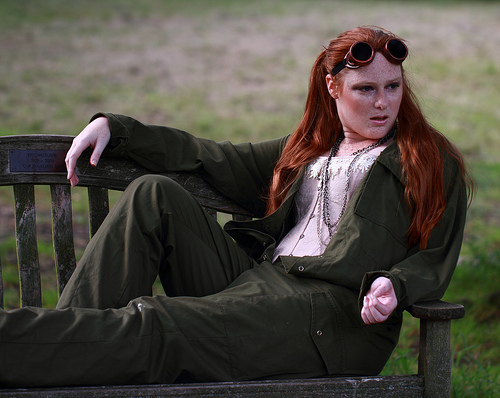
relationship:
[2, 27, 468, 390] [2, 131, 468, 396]
woman on bench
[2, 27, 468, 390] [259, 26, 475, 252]
woman has hair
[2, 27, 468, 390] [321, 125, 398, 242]
woman wearing necklace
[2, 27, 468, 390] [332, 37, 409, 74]
woman wearing goggles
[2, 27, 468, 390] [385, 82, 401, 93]
woman has eye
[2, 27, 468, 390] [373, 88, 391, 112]
woman has nose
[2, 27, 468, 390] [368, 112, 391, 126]
woman has mouth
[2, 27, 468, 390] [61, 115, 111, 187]
woman has hand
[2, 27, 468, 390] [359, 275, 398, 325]
woman has hand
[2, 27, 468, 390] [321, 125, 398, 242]
woman has necklace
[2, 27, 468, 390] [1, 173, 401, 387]
woman wearing pants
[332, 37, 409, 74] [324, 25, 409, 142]
goggles on head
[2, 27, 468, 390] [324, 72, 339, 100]
woman has ear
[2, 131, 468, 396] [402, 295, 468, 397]
bench has arm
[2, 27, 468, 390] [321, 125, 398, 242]
woman modeling necklace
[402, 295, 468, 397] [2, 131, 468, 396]
armrest on bench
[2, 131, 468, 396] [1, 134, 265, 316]
bench has back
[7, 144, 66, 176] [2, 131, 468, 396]
plaque on bench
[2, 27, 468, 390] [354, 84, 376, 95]
woman has eye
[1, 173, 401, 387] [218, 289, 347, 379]
pants have pocket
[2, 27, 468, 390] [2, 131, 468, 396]
woman posing on bench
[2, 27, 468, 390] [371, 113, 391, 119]
woman has lip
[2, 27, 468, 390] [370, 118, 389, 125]
woman has lip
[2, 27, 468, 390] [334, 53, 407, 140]
woman has face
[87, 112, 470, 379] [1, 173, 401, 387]
jacket matches pants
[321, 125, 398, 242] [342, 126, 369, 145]
necklace on neck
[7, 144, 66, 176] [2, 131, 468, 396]
sign on bench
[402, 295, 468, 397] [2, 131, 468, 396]
arm of bench